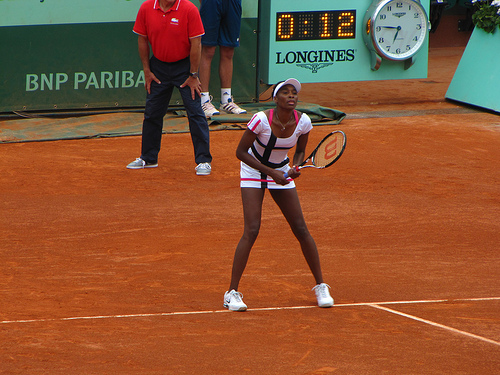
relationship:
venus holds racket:
[219, 75, 342, 313] [284, 127, 345, 174]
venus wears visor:
[219, 75, 342, 313] [276, 76, 304, 96]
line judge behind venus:
[123, 5, 210, 177] [219, 75, 342, 313]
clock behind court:
[263, 16, 385, 34] [1, 190, 222, 374]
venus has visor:
[219, 75, 342, 313] [276, 76, 304, 96]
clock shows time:
[263, 16, 385, 34] [258, 7, 364, 58]